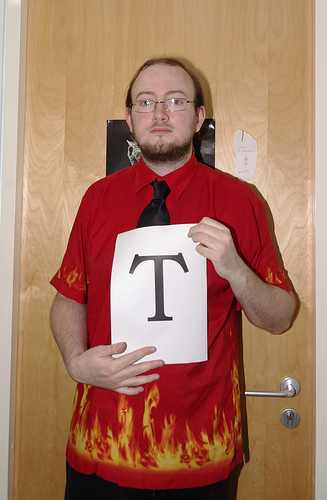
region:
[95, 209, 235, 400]
person is holding a paper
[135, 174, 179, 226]
the tie is black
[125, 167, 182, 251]
the tie is black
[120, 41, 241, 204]
a man with red hair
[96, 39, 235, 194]
a man with facial hair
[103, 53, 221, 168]
a man wearing glasses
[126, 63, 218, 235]
a man wearing a black tie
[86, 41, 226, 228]
a man wearing a tie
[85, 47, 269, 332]
a man wearing a red shirt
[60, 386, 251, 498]
yellow flames on a red shirt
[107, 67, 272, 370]
a man holding a piece of paper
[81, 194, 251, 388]
a piece of paper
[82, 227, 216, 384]
a black T on a piece of paper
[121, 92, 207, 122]
glasses on the face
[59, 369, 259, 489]
flames on the bottom of the shirt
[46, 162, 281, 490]
red and yellow shirt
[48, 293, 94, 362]
hair on the arm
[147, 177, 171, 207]
knot at the top of the tie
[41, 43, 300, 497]
man holding a piece of paper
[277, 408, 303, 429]
lock on the door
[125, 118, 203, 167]
hair on the face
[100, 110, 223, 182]
poster on the door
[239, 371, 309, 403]
silver door handle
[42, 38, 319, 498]
this is a man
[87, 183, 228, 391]
this is a piece of paper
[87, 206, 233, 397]
paper hat T printed on it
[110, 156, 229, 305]
man wearing a tie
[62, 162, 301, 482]
man wearing a red shirt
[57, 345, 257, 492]
flames on the shirt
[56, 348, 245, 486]
the flames are yellow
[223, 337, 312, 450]
a silver door handle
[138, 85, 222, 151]
man wearing eye glasses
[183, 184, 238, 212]
The shirt is red.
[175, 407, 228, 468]
The shirt has a flame graphic on it.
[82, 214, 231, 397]
The man holds a piece of paper.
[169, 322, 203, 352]
The paper is white.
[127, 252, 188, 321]
The letter T is on the paper.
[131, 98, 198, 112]
The man wears eyeglasses.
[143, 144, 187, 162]
The man has facial hair.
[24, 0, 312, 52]
A door is behind the man.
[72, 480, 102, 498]
The pants are black.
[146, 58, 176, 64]
The man has brown hair.